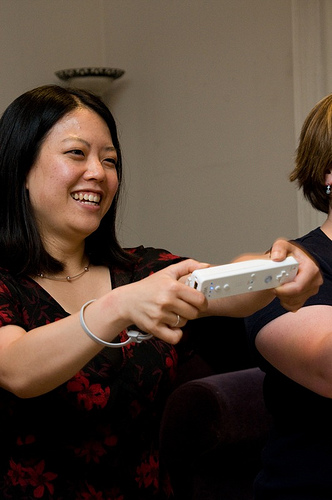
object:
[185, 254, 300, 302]
controller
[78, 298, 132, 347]
strap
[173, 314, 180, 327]
ring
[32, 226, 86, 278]
necklace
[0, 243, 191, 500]
shirt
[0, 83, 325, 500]
woman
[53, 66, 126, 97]
light fixture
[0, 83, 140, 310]
hair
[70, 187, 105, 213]
mouth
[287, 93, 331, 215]
hair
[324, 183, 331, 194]
earring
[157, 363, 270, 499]
chair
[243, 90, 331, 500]
women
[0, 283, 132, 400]
arm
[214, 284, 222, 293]
buttons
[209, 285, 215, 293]
light